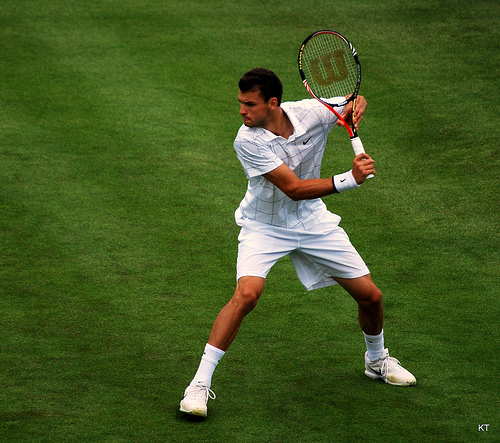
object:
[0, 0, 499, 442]
court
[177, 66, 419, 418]
man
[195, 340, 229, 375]
socks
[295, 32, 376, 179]
racket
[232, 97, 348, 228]
shirt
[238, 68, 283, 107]
hair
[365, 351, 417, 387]
shoes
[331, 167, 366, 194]
wrist band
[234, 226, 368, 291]
shorts